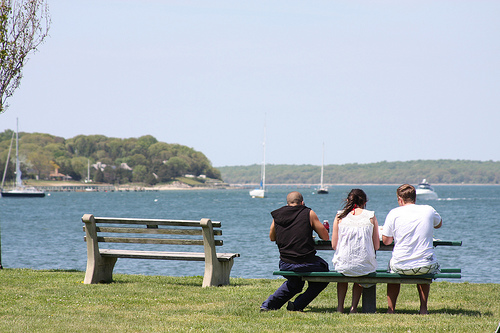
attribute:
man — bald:
[263, 183, 334, 310]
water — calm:
[8, 214, 73, 258]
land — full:
[104, 140, 229, 193]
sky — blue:
[155, 13, 319, 74]